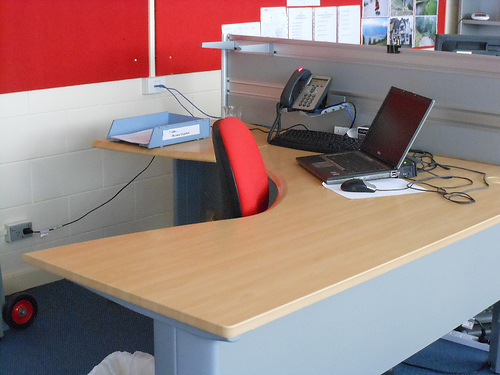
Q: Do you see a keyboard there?
A: Yes, there is a keyboard.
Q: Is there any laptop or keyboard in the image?
A: Yes, there is a keyboard.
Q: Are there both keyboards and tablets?
A: No, there is a keyboard but no tablets.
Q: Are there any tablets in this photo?
A: No, there are no tablets.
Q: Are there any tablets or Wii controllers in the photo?
A: No, there are no tablets or Wii controllers.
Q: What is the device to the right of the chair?
A: The device is a keyboard.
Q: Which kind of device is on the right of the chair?
A: The device is a keyboard.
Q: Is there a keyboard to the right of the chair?
A: Yes, there is a keyboard to the right of the chair.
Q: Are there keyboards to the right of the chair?
A: Yes, there is a keyboard to the right of the chair.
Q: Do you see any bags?
A: Yes, there is a bag.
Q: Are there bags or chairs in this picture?
A: Yes, there is a bag.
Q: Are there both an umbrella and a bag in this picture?
A: No, there is a bag but no umbrellas.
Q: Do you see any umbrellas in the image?
A: No, there are no umbrellas.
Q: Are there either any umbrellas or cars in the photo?
A: No, there are no umbrellas or cars.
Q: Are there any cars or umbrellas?
A: No, there are no umbrellas or cars.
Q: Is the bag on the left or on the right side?
A: The bag is on the left of the image.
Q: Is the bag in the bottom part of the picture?
A: Yes, the bag is in the bottom of the image.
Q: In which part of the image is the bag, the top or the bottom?
A: The bag is in the bottom of the image.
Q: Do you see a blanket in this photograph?
A: No, there are no blankets.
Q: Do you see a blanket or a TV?
A: No, there are no blankets or televisions.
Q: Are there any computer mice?
A: Yes, there is a computer mouse.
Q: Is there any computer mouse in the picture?
A: Yes, there is a computer mouse.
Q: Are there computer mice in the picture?
A: Yes, there is a computer mouse.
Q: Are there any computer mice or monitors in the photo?
A: Yes, there is a computer mouse.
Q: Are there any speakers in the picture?
A: No, there are no speakers.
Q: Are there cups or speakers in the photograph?
A: No, there are no speakers or cups.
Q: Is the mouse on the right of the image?
A: Yes, the mouse is on the right of the image.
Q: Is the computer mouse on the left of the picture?
A: No, the computer mouse is on the right of the image.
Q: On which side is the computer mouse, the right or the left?
A: The computer mouse is on the right of the image.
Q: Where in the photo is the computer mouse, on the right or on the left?
A: The computer mouse is on the right of the image.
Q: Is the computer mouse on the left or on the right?
A: The computer mouse is on the right of the image.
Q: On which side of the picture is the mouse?
A: The mouse is on the right of the image.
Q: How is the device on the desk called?
A: The device is a computer mouse.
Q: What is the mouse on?
A: The mouse is on the desk.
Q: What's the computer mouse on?
A: The mouse is on the desk.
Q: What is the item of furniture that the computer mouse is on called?
A: The piece of furniture is a desk.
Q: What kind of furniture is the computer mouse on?
A: The computer mouse is on the desk.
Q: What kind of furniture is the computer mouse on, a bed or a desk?
A: The computer mouse is on a desk.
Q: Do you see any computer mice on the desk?
A: Yes, there is a computer mouse on the desk.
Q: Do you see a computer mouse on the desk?
A: Yes, there is a computer mouse on the desk.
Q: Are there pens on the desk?
A: No, there is a computer mouse on the desk.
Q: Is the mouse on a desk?
A: Yes, the mouse is on a desk.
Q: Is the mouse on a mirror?
A: No, the mouse is on a desk.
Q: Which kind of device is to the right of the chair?
A: The device is a computer mouse.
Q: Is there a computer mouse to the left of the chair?
A: No, the computer mouse is to the right of the chair.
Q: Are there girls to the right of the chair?
A: No, there is a computer mouse to the right of the chair.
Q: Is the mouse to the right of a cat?
A: No, the mouse is to the right of the chair.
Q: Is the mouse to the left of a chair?
A: No, the mouse is to the right of a chair.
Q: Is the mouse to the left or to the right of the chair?
A: The mouse is to the right of the chair.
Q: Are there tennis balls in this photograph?
A: No, there are no tennis balls.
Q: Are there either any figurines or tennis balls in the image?
A: No, there are no tennis balls or figurines.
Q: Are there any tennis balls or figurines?
A: No, there are no tennis balls or figurines.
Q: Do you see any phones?
A: Yes, there is a phone.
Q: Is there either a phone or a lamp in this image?
A: Yes, there is a phone.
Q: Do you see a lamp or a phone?
A: Yes, there is a phone.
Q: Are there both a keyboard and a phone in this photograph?
A: Yes, there are both a phone and a keyboard.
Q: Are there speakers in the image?
A: No, there are no speakers.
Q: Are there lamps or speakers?
A: No, there are no speakers or lamps.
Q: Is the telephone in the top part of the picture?
A: Yes, the telephone is in the top of the image.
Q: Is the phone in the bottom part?
A: No, the phone is in the top of the image.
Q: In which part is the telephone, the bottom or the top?
A: The telephone is in the top of the image.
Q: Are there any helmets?
A: No, there are no helmets.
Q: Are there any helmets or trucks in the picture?
A: No, there are no helmets or trucks.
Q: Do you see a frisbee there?
A: No, there are no frisbees.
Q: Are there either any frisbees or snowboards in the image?
A: No, there are no frisbees or snowboards.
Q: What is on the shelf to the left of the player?
A: The sticker is on the shelf.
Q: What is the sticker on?
A: The sticker is on the shelf.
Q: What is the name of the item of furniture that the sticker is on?
A: The piece of furniture is a shelf.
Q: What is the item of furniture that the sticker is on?
A: The piece of furniture is a shelf.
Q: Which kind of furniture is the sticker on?
A: The sticker is on the shelf.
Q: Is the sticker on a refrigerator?
A: No, the sticker is on the shelf.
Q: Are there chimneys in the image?
A: No, there are no chimneys.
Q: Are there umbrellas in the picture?
A: No, there are no umbrellas.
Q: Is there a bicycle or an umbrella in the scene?
A: No, there are no umbrellas or bicycles.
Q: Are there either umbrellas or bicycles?
A: No, there are no umbrellas or bicycles.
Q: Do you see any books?
A: No, there are no books.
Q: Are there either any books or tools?
A: No, there are no books or tools.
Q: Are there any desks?
A: Yes, there is a desk.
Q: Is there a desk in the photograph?
A: Yes, there is a desk.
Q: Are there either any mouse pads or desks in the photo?
A: Yes, there is a desk.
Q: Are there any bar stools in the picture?
A: No, there are no bar stools.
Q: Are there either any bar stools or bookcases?
A: No, there are no bar stools or bookcases.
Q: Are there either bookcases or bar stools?
A: No, there are no bar stools or bookcases.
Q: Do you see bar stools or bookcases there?
A: No, there are no bar stools or bookcases.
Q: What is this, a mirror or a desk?
A: This is a desk.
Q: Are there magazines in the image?
A: No, there are no magazines.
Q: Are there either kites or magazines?
A: No, there are no magazines or kites.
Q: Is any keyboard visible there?
A: Yes, there is a keyboard.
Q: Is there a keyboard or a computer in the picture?
A: Yes, there is a keyboard.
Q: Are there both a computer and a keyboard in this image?
A: Yes, there are both a keyboard and a computer.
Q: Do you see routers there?
A: No, there are no routers.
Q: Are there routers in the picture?
A: No, there are no routers.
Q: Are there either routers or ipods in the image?
A: No, there are no routers or ipods.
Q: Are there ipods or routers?
A: No, there are no routers or ipods.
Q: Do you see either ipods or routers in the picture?
A: No, there are no routers or ipods.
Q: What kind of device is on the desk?
A: The device is a keyboard.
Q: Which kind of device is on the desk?
A: The device is a keyboard.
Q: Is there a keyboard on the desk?
A: Yes, there is a keyboard on the desk.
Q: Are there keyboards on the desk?
A: Yes, there is a keyboard on the desk.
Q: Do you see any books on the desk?
A: No, there is a keyboard on the desk.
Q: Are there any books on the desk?
A: No, there is a keyboard on the desk.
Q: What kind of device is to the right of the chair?
A: The device is a keyboard.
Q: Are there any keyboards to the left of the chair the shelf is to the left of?
A: No, the keyboard is to the right of the chair.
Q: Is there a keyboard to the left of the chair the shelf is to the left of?
A: No, the keyboard is to the right of the chair.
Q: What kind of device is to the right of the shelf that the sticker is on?
A: The device is a keyboard.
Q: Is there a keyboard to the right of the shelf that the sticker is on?
A: Yes, there is a keyboard to the right of the shelf.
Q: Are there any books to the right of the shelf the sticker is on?
A: No, there is a keyboard to the right of the shelf.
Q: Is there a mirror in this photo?
A: No, there are no mirrors.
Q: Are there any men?
A: No, there are no men.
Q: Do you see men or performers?
A: No, there are no men or performers.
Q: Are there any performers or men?
A: No, there are no men or performers.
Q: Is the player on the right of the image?
A: Yes, the player is on the right of the image.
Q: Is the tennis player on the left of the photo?
A: No, the player is on the right of the image.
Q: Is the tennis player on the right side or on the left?
A: The player is on the right of the image.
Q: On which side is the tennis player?
A: The player is on the right of the image.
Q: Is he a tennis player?
A: Yes, this is a tennis player.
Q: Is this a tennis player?
A: Yes, this is a tennis player.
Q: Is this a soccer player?
A: No, this is a tennis player.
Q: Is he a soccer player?
A: No, this is a tennis player.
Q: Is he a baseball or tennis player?
A: This is a tennis player.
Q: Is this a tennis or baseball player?
A: This is a tennis player.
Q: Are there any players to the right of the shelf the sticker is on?
A: Yes, there is a player to the right of the shelf.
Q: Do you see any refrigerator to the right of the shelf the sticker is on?
A: No, there is a player to the right of the shelf.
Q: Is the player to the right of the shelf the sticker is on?
A: Yes, the player is to the right of the shelf.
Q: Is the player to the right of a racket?
A: No, the player is to the right of the shelf.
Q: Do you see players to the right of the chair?
A: Yes, there is a player to the right of the chair.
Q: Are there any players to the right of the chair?
A: Yes, there is a player to the right of the chair.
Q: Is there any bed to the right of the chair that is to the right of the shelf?
A: No, there is a player to the right of the chair.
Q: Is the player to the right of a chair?
A: Yes, the player is to the right of a chair.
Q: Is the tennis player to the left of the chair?
A: No, the player is to the right of the chair.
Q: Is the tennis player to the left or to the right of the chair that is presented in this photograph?
A: The player is to the right of the chair.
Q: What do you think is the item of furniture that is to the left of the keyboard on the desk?
A: The piece of furniture is a shelf.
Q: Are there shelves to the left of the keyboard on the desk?
A: Yes, there is a shelf to the left of the keyboard.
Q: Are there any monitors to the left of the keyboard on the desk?
A: No, there is a shelf to the left of the keyboard.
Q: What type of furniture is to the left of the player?
A: The piece of furniture is a shelf.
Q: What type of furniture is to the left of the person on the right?
A: The piece of furniture is a shelf.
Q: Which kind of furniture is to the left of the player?
A: The piece of furniture is a shelf.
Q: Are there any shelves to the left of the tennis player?
A: Yes, there is a shelf to the left of the player.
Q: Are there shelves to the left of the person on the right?
A: Yes, there is a shelf to the left of the player.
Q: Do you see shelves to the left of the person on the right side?
A: Yes, there is a shelf to the left of the player.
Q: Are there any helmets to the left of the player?
A: No, there is a shelf to the left of the player.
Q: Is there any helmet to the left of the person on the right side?
A: No, there is a shelf to the left of the player.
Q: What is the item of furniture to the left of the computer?
A: The piece of furniture is a shelf.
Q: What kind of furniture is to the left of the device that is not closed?
A: The piece of furniture is a shelf.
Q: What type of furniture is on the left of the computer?
A: The piece of furniture is a shelf.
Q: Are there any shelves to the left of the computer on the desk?
A: Yes, there is a shelf to the left of the computer.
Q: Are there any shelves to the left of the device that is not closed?
A: Yes, there is a shelf to the left of the computer.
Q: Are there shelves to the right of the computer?
A: No, the shelf is to the left of the computer.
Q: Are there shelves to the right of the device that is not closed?
A: No, the shelf is to the left of the computer.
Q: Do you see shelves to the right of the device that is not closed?
A: No, the shelf is to the left of the computer.